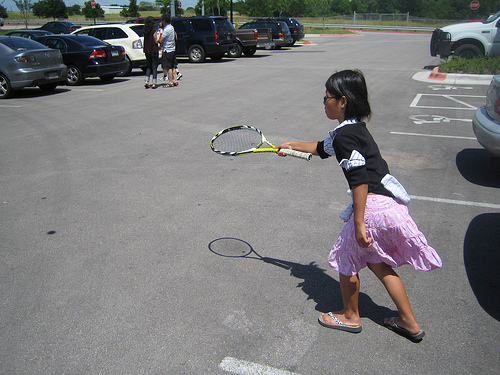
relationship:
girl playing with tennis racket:
[272, 67, 445, 343] [208, 122, 316, 164]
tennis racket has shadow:
[208, 122, 316, 164] [205, 230, 295, 276]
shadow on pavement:
[205, 230, 295, 276] [1, 30, 499, 374]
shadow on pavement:
[42, 228, 59, 237] [1, 30, 499, 374]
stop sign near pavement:
[89, 1, 97, 10] [1, 30, 499, 374]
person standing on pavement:
[141, 19, 159, 90] [1, 30, 499, 374]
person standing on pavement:
[157, 14, 179, 89] [1, 30, 499, 374]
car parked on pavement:
[1, 33, 69, 98] [1, 30, 499, 374]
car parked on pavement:
[30, 31, 134, 90] [1, 30, 499, 374]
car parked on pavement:
[66, 21, 167, 77] [1, 30, 499, 374]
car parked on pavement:
[134, 14, 237, 66] [1, 30, 499, 374]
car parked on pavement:
[221, 19, 275, 63] [1, 30, 499, 374]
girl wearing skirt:
[272, 67, 445, 343] [324, 190, 442, 279]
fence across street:
[285, 12, 453, 29] [309, 22, 450, 39]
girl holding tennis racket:
[272, 67, 445, 343] [208, 122, 316, 164]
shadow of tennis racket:
[205, 230, 295, 276] [208, 122, 316, 164]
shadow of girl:
[261, 255, 402, 330] [272, 67, 445, 343]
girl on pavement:
[272, 67, 445, 343] [1, 30, 499, 374]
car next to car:
[1, 33, 69, 98] [30, 31, 134, 90]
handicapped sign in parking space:
[407, 113, 479, 127] [385, 105, 484, 135]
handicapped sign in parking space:
[428, 83, 472, 94] [420, 81, 495, 98]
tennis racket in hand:
[208, 122, 316, 164] [276, 142, 294, 164]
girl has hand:
[272, 67, 445, 343] [276, 142, 294, 164]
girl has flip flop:
[272, 67, 445, 343] [314, 311, 368, 334]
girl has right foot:
[272, 67, 445, 343] [383, 314, 421, 336]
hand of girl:
[276, 142, 294, 164] [272, 67, 445, 343]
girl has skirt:
[272, 67, 445, 343] [324, 190, 442, 279]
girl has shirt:
[272, 67, 445, 343] [310, 116, 398, 199]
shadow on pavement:
[261, 255, 402, 330] [1, 30, 499, 374]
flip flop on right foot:
[382, 314, 426, 340] [383, 314, 421, 336]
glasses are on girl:
[321, 94, 334, 99] [272, 67, 445, 343]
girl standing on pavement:
[272, 67, 445, 343] [1, 30, 499, 374]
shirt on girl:
[310, 116, 398, 199] [272, 67, 445, 343]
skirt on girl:
[324, 190, 442, 279] [272, 67, 445, 343]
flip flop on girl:
[382, 314, 426, 340] [272, 67, 445, 343]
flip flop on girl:
[314, 311, 368, 334] [272, 67, 445, 343]